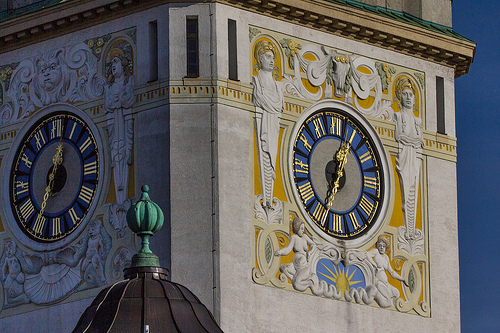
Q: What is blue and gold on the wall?
A: A clock.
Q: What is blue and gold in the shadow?
A: A clock.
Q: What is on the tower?
A: Two clocks.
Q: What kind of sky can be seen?
A: A bright blue sky.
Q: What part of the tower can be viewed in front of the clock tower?
A: The top.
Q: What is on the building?
A: Clocks.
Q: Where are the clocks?
A: On the building.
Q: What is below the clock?
A: The sun.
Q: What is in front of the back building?
A: Another building.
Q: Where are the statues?
A: On the building.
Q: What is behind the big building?
A: The sky.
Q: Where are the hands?
A: On the clocks.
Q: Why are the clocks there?
A: To tell time.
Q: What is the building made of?
A: Stone.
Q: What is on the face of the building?
A: Clocks.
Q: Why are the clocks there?
A: To tell time.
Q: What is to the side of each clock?
A: Statues.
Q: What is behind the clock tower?
A: The sky.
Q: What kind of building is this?
A: A clocktower.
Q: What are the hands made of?
A: Gold.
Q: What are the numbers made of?
A: Gold.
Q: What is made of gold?
A: The numbers.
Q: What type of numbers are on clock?
A: Roman.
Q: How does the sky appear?
A: Clear.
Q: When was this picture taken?
A: Day time.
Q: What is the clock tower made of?
A: Cement.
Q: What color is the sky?
A: Blue.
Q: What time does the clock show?
A: 12:35.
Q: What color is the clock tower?
A: Gold and blue.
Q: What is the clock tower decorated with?
A: People.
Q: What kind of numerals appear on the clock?
A: Roman.